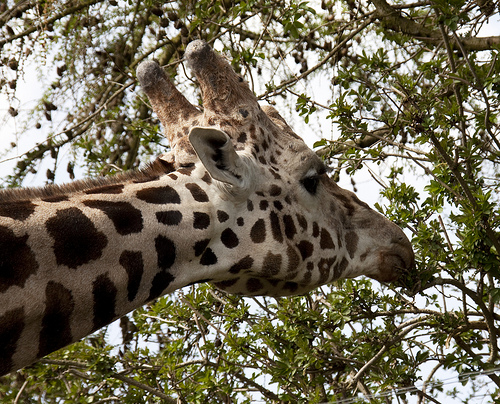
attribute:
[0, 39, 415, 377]
giraffe — white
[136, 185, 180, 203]
spot — brown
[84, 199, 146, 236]
spot — brown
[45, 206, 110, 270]
spot — brown, brow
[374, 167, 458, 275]
foilage — green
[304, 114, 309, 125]
leaf — green, small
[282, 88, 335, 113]
branch — brown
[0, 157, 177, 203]
mane — thin, brown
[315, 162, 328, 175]
marking — black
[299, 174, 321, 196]
eye — black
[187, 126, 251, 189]
ear — white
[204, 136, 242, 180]
inside — black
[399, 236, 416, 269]
nose — brown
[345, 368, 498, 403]
wire — thin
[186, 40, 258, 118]
horn — light brown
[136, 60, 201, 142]
horn — light brown